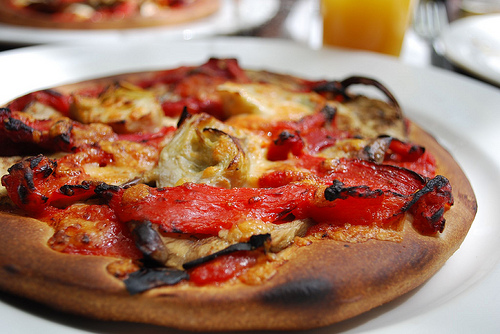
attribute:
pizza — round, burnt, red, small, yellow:
[3, 59, 471, 324]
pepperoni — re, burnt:
[118, 177, 263, 232]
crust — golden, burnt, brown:
[23, 255, 113, 321]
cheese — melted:
[90, 139, 154, 186]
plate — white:
[444, 13, 500, 84]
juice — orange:
[325, 0, 409, 46]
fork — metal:
[410, 1, 447, 68]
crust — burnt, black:
[258, 273, 350, 320]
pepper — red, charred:
[310, 158, 444, 227]